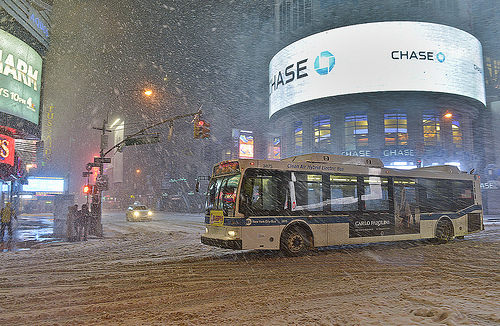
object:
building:
[67, 0, 500, 210]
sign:
[267, 21, 486, 122]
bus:
[199, 154, 484, 257]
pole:
[86, 170, 90, 205]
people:
[0, 202, 19, 242]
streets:
[0, 158, 500, 326]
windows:
[312, 119, 329, 150]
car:
[125, 205, 153, 222]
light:
[145, 90, 153, 95]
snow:
[156, 8, 175, 30]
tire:
[280, 224, 309, 257]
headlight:
[133, 211, 140, 215]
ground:
[361, 246, 412, 298]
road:
[0, 213, 499, 326]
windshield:
[205, 174, 241, 212]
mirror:
[239, 207, 246, 215]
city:
[0, 0, 500, 326]